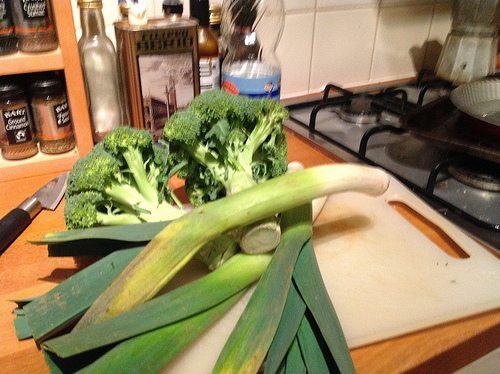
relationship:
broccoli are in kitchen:
[157, 88, 290, 257] [2, 2, 496, 372]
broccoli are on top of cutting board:
[157, 88, 290, 257] [62, 161, 495, 373]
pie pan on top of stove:
[447, 73, 499, 132] [280, 68, 499, 225]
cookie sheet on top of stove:
[399, 103, 497, 159] [280, 68, 499, 225]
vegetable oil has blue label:
[213, 2, 292, 115] [220, 70, 285, 97]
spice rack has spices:
[1, 1, 95, 185] [5, 80, 69, 154]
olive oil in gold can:
[108, 12, 203, 127] [121, 31, 193, 118]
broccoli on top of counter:
[56, 92, 299, 251] [6, 160, 461, 370]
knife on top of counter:
[2, 167, 72, 263] [6, 160, 461, 370]